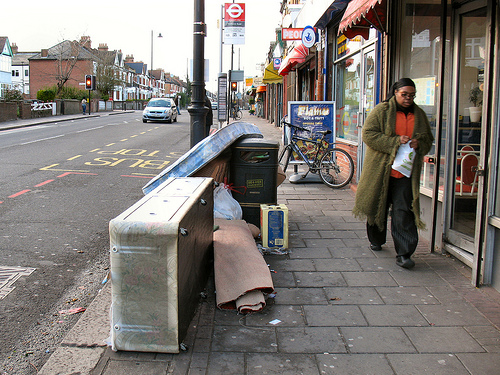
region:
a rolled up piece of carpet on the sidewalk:
[213, 219, 273, 314]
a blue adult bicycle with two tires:
[278, 118, 355, 187]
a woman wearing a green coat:
[354, 75, 434, 270]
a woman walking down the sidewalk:
[356, 77, 434, 272]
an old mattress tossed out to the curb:
[140, 119, 264, 195]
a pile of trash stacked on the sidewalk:
[110, 118, 289, 353]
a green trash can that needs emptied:
[232, 135, 277, 230]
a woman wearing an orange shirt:
[355, 77, 433, 269]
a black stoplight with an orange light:
[83, 73, 96, 114]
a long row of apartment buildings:
[24, 35, 191, 114]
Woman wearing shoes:
[359, 234, 433, 271]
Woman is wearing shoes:
[369, 232, 414, 272]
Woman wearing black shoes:
[363, 236, 418, 273]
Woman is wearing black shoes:
[365, 234, 418, 271]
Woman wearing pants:
[364, 171, 420, 258]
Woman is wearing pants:
[363, 166, 421, 258]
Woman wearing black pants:
[363, 173, 421, 258]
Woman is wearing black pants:
[364, 172, 422, 261]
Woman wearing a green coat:
[352, 94, 432, 237]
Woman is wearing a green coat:
[351, 92, 435, 232]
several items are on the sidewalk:
[100, 105, 289, 360]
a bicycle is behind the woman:
[276, 116, 355, 191]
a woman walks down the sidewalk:
[358, 71, 446, 286]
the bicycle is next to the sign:
[268, 98, 354, 193]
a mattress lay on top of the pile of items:
[138, 113, 265, 193]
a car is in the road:
[126, 90, 176, 131]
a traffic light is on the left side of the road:
[80, 70, 96, 96]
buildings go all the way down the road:
[0, 29, 218, 111]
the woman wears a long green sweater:
[354, 99, 436, 227]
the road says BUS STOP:
[78, 138, 185, 181]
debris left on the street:
[87, 73, 306, 368]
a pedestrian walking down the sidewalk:
[335, 39, 457, 307]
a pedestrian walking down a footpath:
[335, 59, 455, 317]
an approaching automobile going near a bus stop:
[12, 26, 184, 216]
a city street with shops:
[10, 0, 492, 354]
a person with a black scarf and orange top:
[347, 58, 452, 277]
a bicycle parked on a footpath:
[245, 98, 359, 198]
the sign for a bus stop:
[209, 0, 259, 150]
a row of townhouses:
[17, 34, 192, 123]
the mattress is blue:
[208, 140, 223, 152]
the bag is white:
[217, 195, 231, 208]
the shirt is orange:
[397, 118, 409, 132]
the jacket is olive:
[370, 170, 380, 192]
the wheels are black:
[178, 226, 189, 238]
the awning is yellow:
[266, 67, 276, 78]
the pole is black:
[191, 52, 208, 80]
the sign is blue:
[293, 112, 310, 127]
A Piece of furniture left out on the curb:
[95, 178, 220, 360]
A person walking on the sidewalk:
[352, 79, 433, 278]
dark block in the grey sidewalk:
[336, 320, 417, 351]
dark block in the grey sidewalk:
[275, 320, 346, 355]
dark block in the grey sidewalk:
[300, 302, 368, 322]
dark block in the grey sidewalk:
[322, 280, 382, 305]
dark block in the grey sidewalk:
[265, 278, 331, 301]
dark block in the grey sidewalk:
[215, 325, 281, 356]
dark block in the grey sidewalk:
[290, 267, 346, 287]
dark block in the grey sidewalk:
[315, 252, 363, 274]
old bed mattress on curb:
[122, 119, 264, 198]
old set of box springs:
[102, 169, 219, 356]